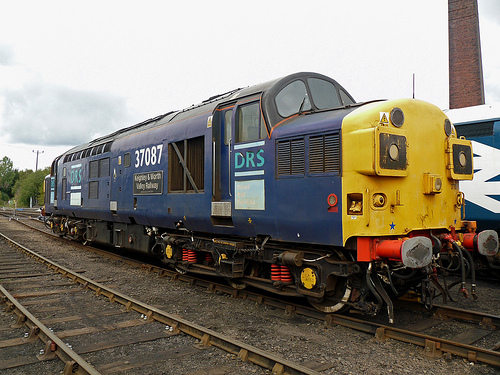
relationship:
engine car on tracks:
[40, 70, 479, 324] [0, 212, 499, 367]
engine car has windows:
[40, 70, 479, 324] [282, 82, 387, 115]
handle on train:
[207, 142, 231, 204] [208, 136, 219, 179]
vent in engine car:
[272, 130, 341, 175] [40, 70, 479, 324]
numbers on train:
[133, 145, 163, 166] [51, 69, 481, 324]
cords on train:
[350, 259, 407, 329] [51, 69, 481, 324]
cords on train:
[433, 230, 480, 311] [51, 69, 481, 324]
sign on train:
[232, 150, 267, 170] [51, 69, 481, 324]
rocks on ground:
[241, 317, 461, 373] [1, 209, 499, 373]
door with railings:
[210, 101, 235, 213] [208, 138, 233, 196]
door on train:
[210, 101, 235, 213] [4, 40, 464, 306]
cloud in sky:
[32, 36, 182, 111] [14, 14, 207, 146]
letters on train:
[231, 142, 276, 179] [51, 69, 481, 324]